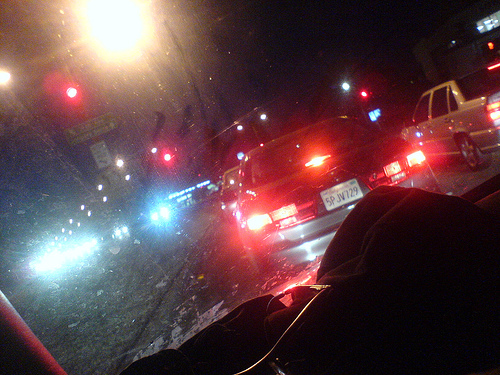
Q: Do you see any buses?
A: No, there are no buses.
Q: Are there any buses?
A: No, there are no buses.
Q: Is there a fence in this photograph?
A: No, there are no fences.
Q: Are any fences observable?
A: No, there are no fences.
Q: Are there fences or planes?
A: No, there are no fences or planes.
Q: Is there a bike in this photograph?
A: No, there are no bikes.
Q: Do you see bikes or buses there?
A: No, there are no bikes or buses.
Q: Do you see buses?
A: No, there are no buses.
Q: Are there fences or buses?
A: No, there are no buses or fences.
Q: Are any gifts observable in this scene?
A: No, there are no gifts.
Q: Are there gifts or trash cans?
A: No, there are no gifts or trash cans.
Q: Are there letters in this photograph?
A: Yes, there are letters.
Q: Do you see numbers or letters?
A: Yes, there are letters.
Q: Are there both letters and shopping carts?
A: No, there are letters but no shopping carts.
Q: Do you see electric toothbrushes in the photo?
A: No, there are no electric toothbrushes.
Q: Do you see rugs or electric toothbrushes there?
A: No, there are no electric toothbrushes or rugs.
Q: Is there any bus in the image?
A: No, there are no buses.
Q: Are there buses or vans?
A: No, there are no buses or vans.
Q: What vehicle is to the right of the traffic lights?
A: The vehicle is a car.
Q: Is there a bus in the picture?
A: No, there are no buses.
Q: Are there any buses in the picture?
A: No, there are no buses.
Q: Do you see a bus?
A: No, there are no buses.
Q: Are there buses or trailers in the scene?
A: No, there are no buses or trailers.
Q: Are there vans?
A: No, there are no vans.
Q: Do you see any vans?
A: No, there are no vans.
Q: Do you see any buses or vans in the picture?
A: No, there are no vans or buses.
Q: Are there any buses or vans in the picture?
A: No, there are no vans or buses.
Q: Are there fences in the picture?
A: No, there are no fences.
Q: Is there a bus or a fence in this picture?
A: No, there are no fences or buses.